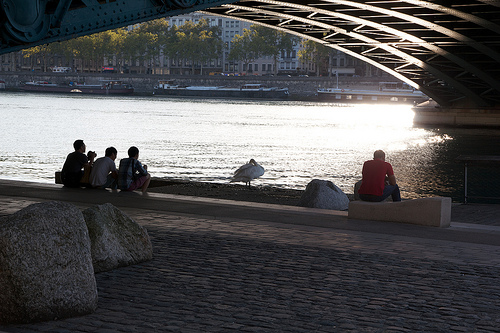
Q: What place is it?
A: It is a river.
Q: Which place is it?
A: It is a river.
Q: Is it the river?
A: Yes, it is the river.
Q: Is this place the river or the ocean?
A: It is the river.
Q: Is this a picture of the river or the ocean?
A: It is showing the river.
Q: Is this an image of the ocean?
A: No, the picture is showing the river.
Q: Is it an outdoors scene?
A: Yes, it is outdoors.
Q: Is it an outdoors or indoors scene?
A: It is outdoors.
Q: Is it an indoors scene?
A: No, it is outdoors.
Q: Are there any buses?
A: No, there are no buses.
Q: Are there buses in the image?
A: No, there are no buses.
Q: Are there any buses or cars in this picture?
A: No, there are no buses or cars.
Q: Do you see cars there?
A: No, there are no cars.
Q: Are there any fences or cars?
A: No, there are no cars or fences.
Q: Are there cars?
A: No, there are no cars.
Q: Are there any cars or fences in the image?
A: No, there are no cars or fences.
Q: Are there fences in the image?
A: No, there are no fences.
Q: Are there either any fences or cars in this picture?
A: No, there are no fences or cars.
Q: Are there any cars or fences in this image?
A: No, there are no fences or cars.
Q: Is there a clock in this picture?
A: No, there are no clocks.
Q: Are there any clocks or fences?
A: No, there are no clocks or fences.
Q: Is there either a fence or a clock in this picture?
A: No, there are no clocks or fences.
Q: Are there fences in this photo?
A: No, there are no fences.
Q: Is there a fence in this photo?
A: No, there are no fences.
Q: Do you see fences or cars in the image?
A: No, there are no fences or cars.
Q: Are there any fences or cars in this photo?
A: No, there are no fences or cars.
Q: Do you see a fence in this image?
A: No, there are no fences.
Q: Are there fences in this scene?
A: No, there are no fences.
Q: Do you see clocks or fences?
A: No, there are no fences or clocks.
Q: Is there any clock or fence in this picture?
A: No, there are no fences or clocks.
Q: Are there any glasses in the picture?
A: No, there are no glasses.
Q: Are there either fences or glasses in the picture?
A: No, there are no glasses or fences.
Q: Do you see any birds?
A: Yes, there is a bird.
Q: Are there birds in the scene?
A: Yes, there is a bird.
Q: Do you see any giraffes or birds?
A: Yes, there is a bird.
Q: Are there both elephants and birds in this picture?
A: No, there is a bird but no elephants.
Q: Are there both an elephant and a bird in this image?
A: No, there is a bird but no elephants.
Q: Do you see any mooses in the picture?
A: No, there are no mooses.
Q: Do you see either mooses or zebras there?
A: No, there are no mooses or zebras.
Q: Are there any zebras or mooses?
A: No, there are no mooses or zebras.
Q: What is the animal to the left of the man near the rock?
A: The animal is a bird.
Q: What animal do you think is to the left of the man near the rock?
A: The animal is a bird.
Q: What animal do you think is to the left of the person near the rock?
A: The animal is a bird.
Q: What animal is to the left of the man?
A: The animal is a bird.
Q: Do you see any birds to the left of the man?
A: Yes, there is a bird to the left of the man.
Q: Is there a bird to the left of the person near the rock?
A: Yes, there is a bird to the left of the man.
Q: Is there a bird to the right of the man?
A: No, the bird is to the left of the man.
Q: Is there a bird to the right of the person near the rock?
A: No, the bird is to the left of the man.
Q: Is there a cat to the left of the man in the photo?
A: No, there is a bird to the left of the man.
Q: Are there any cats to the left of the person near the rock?
A: No, there is a bird to the left of the man.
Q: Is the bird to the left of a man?
A: Yes, the bird is to the left of a man.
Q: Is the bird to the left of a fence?
A: No, the bird is to the left of a man.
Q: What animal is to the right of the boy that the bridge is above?
A: The animal is a bird.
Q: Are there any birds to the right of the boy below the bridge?
A: Yes, there is a bird to the right of the boy.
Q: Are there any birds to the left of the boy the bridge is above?
A: No, the bird is to the right of the boy.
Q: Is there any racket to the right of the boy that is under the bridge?
A: No, there is a bird to the right of the boy.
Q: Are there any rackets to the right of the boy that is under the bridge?
A: No, there is a bird to the right of the boy.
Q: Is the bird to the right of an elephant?
A: No, the bird is to the right of the boy.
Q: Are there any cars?
A: No, there are no cars.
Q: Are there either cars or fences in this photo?
A: No, there are no cars or fences.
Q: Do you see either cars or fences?
A: No, there are no cars or fences.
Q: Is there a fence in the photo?
A: No, there are no fences.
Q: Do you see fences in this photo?
A: No, there are no fences.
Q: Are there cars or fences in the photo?
A: No, there are no fences or cars.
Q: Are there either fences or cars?
A: No, there are no fences or cars.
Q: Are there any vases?
A: No, there are no vases.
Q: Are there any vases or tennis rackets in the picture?
A: No, there are no vases or tennis rackets.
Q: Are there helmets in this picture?
A: No, there are no helmets.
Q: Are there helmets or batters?
A: No, there are no helmets or batters.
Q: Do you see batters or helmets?
A: No, there are no helmets or batters.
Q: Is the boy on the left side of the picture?
A: Yes, the boy is on the left of the image.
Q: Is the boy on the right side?
A: No, the boy is on the left of the image.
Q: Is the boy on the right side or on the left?
A: The boy is on the left of the image.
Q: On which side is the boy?
A: The boy is on the left of the image.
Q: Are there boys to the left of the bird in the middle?
A: Yes, there is a boy to the left of the bird.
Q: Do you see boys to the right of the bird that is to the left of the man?
A: No, the boy is to the left of the bird.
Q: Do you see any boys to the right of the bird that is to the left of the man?
A: No, the boy is to the left of the bird.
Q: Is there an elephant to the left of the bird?
A: No, there is a boy to the left of the bird.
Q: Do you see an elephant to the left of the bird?
A: No, there is a boy to the left of the bird.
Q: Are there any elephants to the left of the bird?
A: No, there is a boy to the left of the bird.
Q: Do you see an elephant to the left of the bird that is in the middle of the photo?
A: No, there is a boy to the left of the bird.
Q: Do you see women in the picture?
A: No, there are no women.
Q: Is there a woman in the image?
A: No, there are no women.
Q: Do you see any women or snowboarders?
A: No, there are no women or snowboarders.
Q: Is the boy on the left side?
A: Yes, the boy is on the left of the image.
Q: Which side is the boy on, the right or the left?
A: The boy is on the left of the image.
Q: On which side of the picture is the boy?
A: The boy is on the left of the image.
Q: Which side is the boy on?
A: The boy is on the left of the image.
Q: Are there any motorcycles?
A: No, there are no motorcycles.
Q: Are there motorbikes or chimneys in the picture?
A: No, there are no motorbikes or chimneys.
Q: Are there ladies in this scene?
A: No, there are no ladies.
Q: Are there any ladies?
A: No, there are no ladies.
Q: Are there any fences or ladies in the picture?
A: No, there are no ladies or fences.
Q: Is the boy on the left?
A: Yes, the boy is on the left of the image.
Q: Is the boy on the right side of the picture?
A: No, the boy is on the left of the image.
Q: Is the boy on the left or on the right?
A: The boy is on the left of the image.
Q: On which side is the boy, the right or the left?
A: The boy is on the left of the image.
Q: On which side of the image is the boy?
A: The boy is on the left of the image.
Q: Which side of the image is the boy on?
A: The boy is on the left of the image.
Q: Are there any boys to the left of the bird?
A: Yes, there is a boy to the left of the bird.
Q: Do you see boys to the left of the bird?
A: Yes, there is a boy to the left of the bird.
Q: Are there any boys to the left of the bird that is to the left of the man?
A: Yes, there is a boy to the left of the bird.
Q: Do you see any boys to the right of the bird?
A: No, the boy is to the left of the bird.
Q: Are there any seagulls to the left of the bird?
A: No, there is a boy to the left of the bird.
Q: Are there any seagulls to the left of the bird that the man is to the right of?
A: No, there is a boy to the left of the bird.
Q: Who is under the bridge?
A: The boy is under the bridge.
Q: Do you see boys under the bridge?
A: Yes, there is a boy under the bridge.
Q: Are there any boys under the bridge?
A: Yes, there is a boy under the bridge.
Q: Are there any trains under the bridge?
A: No, there is a boy under the bridge.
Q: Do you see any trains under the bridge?
A: No, there is a boy under the bridge.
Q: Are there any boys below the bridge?
A: Yes, there is a boy below the bridge.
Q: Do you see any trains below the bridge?
A: No, there is a boy below the bridge.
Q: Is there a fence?
A: No, there are no fences.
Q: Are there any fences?
A: No, there are no fences.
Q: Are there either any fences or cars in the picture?
A: No, there are no fences or cars.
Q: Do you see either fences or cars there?
A: No, there are no fences or cars.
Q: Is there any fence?
A: No, there are no fences.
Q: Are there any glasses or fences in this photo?
A: No, there are no fences or glasses.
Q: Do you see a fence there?
A: No, there are no fences.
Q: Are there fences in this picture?
A: No, there are no fences.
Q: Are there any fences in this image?
A: No, there are no fences.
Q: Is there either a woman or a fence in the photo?
A: No, there are no fences or women.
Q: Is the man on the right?
A: Yes, the man is on the right of the image.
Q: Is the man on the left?
A: No, the man is on the right of the image.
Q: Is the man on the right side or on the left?
A: The man is on the right of the image.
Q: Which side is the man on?
A: The man is on the right of the image.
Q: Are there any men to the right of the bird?
A: Yes, there is a man to the right of the bird.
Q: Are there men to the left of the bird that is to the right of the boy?
A: No, the man is to the right of the bird.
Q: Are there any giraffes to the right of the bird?
A: No, there is a man to the right of the bird.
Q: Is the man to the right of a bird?
A: Yes, the man is to the right of a bird.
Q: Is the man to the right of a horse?
A: No, the man is to the right of a bird.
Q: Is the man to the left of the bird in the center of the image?
A: No, the man is to the right of the bird.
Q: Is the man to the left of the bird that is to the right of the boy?
A: No, the man is to the right of the bird.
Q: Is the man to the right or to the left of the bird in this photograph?
A: The man is to the right of the bird.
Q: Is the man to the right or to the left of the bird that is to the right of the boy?
A: The man is to the right of the bird.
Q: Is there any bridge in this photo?
A: Yes, there is a bridge.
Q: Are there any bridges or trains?
A: Yes, there is a bridge.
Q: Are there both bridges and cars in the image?
A: No, there is a bridge but no cars.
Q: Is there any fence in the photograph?
A: No, there are no fences.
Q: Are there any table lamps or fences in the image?
A: No, there are no fences or table lamps.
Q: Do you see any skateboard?
A: No, there are no skateboards.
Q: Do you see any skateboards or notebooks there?
A: No, there are no skateboards or notebooks.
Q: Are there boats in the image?
A: Yes, there is a boat.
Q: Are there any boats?
A: Yes, there is a boat.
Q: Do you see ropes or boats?
A: Yes, there is a boat.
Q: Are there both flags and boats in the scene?
A: No, there is a boat but no flags.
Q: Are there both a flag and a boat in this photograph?
A: No, there is a boat but no flags.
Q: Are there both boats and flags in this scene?
A: No, there is a boat but no flags.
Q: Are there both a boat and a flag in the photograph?
A: No, there is a boat but no flags.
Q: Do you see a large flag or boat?
A: Yes, there is a large boat.